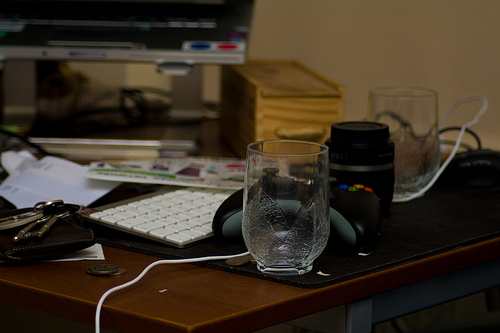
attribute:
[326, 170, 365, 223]
button — blue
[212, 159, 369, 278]
controller — game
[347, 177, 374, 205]
button — yellow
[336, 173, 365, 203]
button — red, game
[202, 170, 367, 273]
controller — game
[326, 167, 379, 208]
button — blue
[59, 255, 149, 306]
wire — white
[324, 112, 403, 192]
camera lens — black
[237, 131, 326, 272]
glass — clear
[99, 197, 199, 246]
keyboard — apple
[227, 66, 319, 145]
box — small, wood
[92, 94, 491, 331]
wire — white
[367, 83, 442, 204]
glass — clear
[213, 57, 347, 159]
box — wooden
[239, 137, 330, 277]
glass — empty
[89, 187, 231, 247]
keyboard — flat, white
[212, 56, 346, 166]
storage box — wooden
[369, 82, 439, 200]
glass — empty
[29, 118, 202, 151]
dvd player — small, digital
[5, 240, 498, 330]
desk — dark brown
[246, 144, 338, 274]
glass — empty